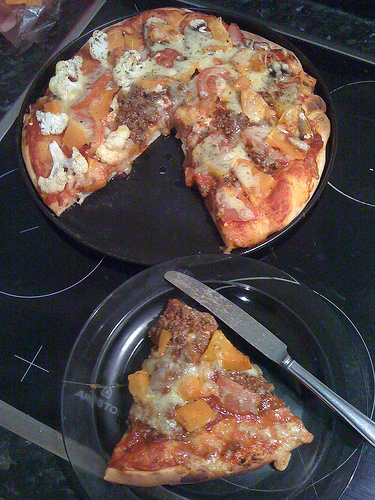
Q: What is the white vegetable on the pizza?
A: Cauliflower.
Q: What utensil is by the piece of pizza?
A: A knife.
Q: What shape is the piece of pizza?
A: A triangle.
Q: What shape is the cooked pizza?
A: A Circle.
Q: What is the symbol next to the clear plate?
A: A plus sign.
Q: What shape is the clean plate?
A: A circle.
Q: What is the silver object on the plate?
A: A knife.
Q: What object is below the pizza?
A: A plate.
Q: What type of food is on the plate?
A: Pizza.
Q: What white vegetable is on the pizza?
A: Cauliflower.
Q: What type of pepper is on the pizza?
A: Orange bell.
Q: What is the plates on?
A: Stove top.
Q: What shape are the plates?
A: Round.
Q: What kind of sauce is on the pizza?
A: Tomato.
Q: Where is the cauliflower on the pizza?
A: Left side.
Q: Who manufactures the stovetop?
A: Armstrong.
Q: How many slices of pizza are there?
A: Four.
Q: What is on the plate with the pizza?
A: Knife.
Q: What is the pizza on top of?
A: Stove Top.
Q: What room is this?
A: Kitchen.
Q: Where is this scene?
A: A house.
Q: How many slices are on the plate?
A: One.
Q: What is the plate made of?
A: Glass.